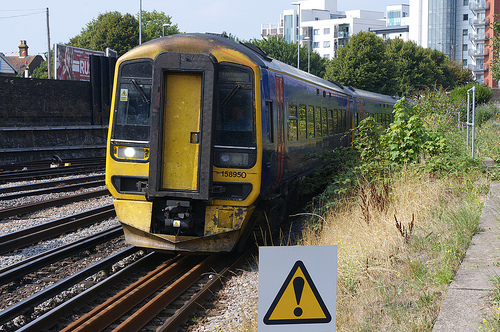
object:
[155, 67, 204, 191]
door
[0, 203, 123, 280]
train tracks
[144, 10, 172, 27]
leaves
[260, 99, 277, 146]
window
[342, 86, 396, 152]
cars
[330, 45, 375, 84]
leaves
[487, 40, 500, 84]
leaves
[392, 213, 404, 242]
leaves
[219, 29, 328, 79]
tree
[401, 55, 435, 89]
leaves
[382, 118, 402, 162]
leaves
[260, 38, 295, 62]
leaves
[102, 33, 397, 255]
train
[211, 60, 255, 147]
window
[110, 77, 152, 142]
window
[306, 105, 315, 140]
window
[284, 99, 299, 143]
window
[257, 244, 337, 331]
sign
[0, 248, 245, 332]
tracks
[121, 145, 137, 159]
light